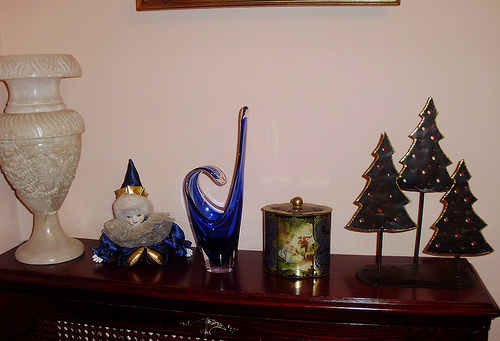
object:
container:
[261, 195, 331, 279]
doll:
[92, 158, 194, 267]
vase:
[0, 53, 85, 265]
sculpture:
[183, 106, 250, 273]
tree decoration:
[344, 96, 493, 287]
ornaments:
[453, 232, 460, 238]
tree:
[422, 158, 495, 260]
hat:
[115, 158, 149, 197]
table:
[2, 237, 499, 340]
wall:
[0, 0, 499, 339]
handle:
[179, 317, 240, 338]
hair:
[113, 194, 155, 222]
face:
[125, 212, 145, 226]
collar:
[100, 212, 173, 246]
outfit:
[92, 211, 194, 267]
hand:
[91, 252, 104, 263]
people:
[296, 235, 312, 261]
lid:
[261, 195, 333, 217]